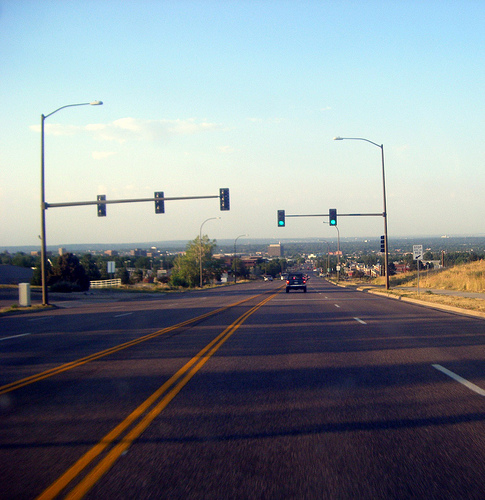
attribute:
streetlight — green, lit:
[274, 208, 286, 228]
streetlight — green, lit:
[328, 206, 337, 225]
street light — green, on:
[325, 205, 339, 228]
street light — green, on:
[275, 206, 286, 229]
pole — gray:
[335, 115, 411, 324]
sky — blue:
[205, 26, 317, 101]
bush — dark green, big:
[46, 245, 92, 293]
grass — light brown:
[337, 258, 483, 316]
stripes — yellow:
[18, 280, 314, 495]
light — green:
[276, 205, 342, 227]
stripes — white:
[432, 360, 483, 397]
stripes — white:
[332, 302, 342, 309]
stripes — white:
[113, 309, 135, 318]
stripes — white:
[165, 302, 178, 308]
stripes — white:
[0, 330, 33, 341]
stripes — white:
[323, 294, 330, 301]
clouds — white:
[167, 86, 453, 224]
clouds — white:
[106, 121, 207, 152]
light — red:
[297, 277, 308, 290]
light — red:
[279, 277, 292, 286]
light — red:
[316, 206, 357, 238]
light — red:
[268, 209, 286, 226]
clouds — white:
[70, 145, 104, 167]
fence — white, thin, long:
[89, 280, 141, 290]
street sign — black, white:
[408, 240, 428, 260]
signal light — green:
[328, 217, 337, 226]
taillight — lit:
[285, 278, 290, 285]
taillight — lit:
[303, 279, 306, 285]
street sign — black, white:
[410, 240, 425, 290]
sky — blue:
[0, 0, 485, 246]